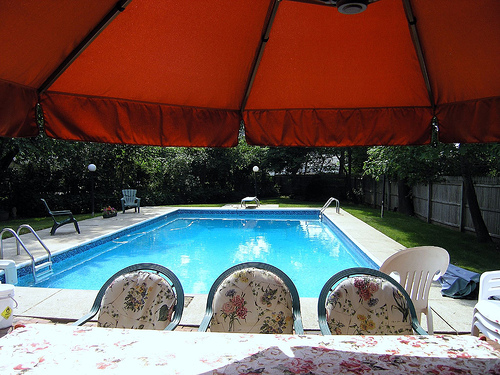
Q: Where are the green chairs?
A: Beside the pool.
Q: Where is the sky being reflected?
A: Pool.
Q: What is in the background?
A: Trees.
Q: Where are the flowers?
A: Table and chairs.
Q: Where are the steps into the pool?
A: Left side of the pool.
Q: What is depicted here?
A: A red patio umbrella.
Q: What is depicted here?
A: A padded patio chair.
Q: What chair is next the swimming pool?
A: A white plastic chair.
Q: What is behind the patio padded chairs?
A: A large blue pool.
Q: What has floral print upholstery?
A: Three chairs.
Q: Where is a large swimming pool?
A: In the backyard.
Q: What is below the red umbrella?
A: Outdoor tables and chairs.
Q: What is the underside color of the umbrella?
A: Red.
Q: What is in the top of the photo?
A: Umbrella.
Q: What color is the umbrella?
A: Red.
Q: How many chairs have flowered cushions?
A: Three.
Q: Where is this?
A: Backyard.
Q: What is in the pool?
A: Water.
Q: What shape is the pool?
A: Rectangle.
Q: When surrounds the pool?
A: Fence.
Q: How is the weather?
A: Sunny.